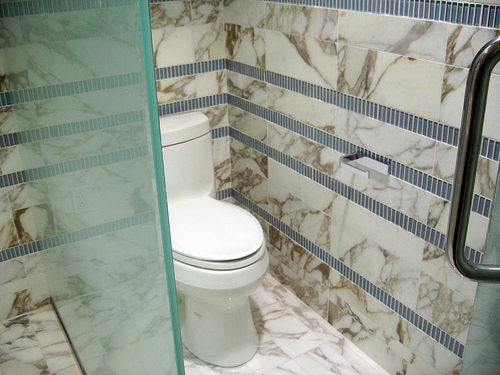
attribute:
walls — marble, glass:
[30, 57, 152, 194]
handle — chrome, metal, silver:
[456, 51, 487, 152]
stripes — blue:
[317, 91, 451, 137]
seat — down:
[176, 191, 245, 246]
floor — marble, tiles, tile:
[298, 306, 333, 351]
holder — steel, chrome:
[341, 155, 381, 182]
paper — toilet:
[298, 142, 398, 181]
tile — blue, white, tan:
[273, 312, 330, 365]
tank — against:
[150, 112, 222, 182]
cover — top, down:
[199, 201, 271, 261]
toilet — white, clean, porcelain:
[169, 133, 288, 308]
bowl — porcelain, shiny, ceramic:
[181, 245, 302, 302]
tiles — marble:
[261, 300, 327, 353]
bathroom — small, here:
[32, 22, 451, 358]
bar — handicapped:
[443, 156, 497, 242]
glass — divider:
[84, 70, 184, 225]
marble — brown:
[263, 12, 375, 73]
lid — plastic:
[176, 210, 238, 248]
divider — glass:
[129, 40, 197, 162]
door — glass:
[53, 138, 160, 268]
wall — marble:
[283, 19, 383, 139]